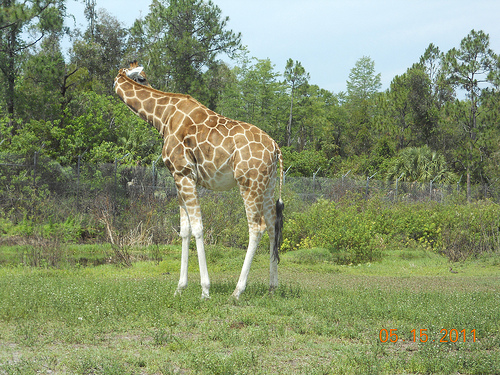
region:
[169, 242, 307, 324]
Tall giraffe standing in field.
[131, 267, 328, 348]
Field has green grass in it.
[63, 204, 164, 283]
Brown sticks sticking out of ground.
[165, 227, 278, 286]
Bottom of giraffe's legs are white.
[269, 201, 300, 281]
Black hair on the end of giraffe's tail.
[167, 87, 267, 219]
Giraffe is brown and white.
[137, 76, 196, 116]
Giraffe has brown hair on neck.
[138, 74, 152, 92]
Giraffe has black eyelashes.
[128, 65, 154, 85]
Giraffe has white ear.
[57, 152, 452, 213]
Tall fencing behind giraffe.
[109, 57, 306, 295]
giraffe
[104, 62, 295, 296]
spotted giraffe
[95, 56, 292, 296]
spotted giraffe looking backward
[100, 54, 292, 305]
tan and brown spotted giraffe looking backward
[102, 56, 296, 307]
tan and brown spotted giraffe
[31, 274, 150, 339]
short green and brown grass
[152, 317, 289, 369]
short green and brown grass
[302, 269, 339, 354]
short green and brown grass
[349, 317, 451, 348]
short green and brown grass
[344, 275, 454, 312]
short green and brown grass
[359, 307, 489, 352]
orange date stamp on phote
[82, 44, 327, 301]
tall giraffe in grass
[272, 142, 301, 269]
long tail of giraffe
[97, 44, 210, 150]
giraffe with head turned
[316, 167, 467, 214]
tall fence around giraffe habitat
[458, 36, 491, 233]
tall tree with green leaves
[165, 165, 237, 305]
long legs of giraffe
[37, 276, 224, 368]
green grass in field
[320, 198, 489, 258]
bushed in front of fence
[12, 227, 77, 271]
brown bushes in field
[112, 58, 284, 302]
a giraffe contained in a wildlife park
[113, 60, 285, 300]
brown and white giraffe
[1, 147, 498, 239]
a fence securing the giraffe's habitat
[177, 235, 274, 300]
white legs on the giraffe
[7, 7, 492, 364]
giraffe standing alone in the habitat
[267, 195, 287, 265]
black hair on the end of giraffe's tail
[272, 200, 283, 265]
long black hair on the tail of the giraffe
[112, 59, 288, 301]
giraffe standing on the ground looking backward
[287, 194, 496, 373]
green grass and bushes in the giraffe's habitat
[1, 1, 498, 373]
giraffe looking to the side at a wild park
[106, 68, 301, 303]
giraffe looking backward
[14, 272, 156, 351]
short green and brown grass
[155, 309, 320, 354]
short green and brown grass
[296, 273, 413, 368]
short green and brown grass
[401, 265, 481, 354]
short green and brown grass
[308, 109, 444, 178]
bushes with green leaves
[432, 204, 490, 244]
bushes with green leaves